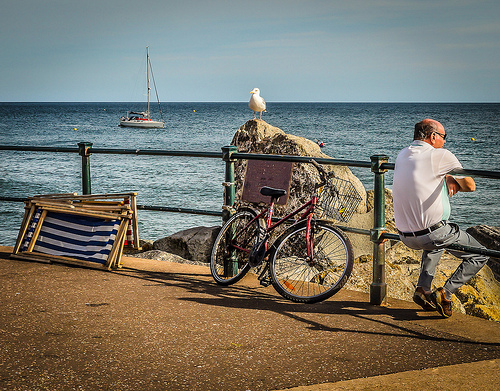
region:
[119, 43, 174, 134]
sailboat sailing in the middle of the ocean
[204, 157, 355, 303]
red bicycle leaning on fence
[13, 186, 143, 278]
beach chairs stacked next to fence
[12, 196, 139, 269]
blue and white beach chairs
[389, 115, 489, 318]
man sitting on fence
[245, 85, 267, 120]
white seagull sitting on top of large rock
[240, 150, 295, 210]
plaque embedded into large rock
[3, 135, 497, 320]
fence is metal and green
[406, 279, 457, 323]
man is wearing brown shoes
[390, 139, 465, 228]
man is wearing a white shirt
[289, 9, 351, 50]
this is the sky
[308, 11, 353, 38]
the sky is blue in color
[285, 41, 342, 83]
the clouds are white in color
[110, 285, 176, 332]
this is the ground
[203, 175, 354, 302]
this is a bicycle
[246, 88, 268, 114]
this is a bird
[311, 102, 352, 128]
this is the water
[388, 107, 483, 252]
this is a man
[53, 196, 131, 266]
Blue and white stand on the side.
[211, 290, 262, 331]
Blue and white stand on the side.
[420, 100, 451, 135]
Blue and white stand on the side.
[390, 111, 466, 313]
the man is sitted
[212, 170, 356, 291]
this is a bike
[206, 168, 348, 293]
the bike is parked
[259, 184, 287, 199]
this is the seat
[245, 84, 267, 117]
the bird is white in color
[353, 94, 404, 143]
this is the sky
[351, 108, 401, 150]
the water is calm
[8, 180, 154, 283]
several beach chairs stacked against a railing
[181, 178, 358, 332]
a bike leaning against a fence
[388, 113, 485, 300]
a man sitting on a fence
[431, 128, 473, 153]
a man wearing glasses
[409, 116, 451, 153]
a man with a balding head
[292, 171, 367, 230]
a metal basket attached to a bike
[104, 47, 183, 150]
a boat floating in the water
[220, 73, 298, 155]
a white seagull sitting on a rock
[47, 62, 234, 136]
a boat floating in the ocean